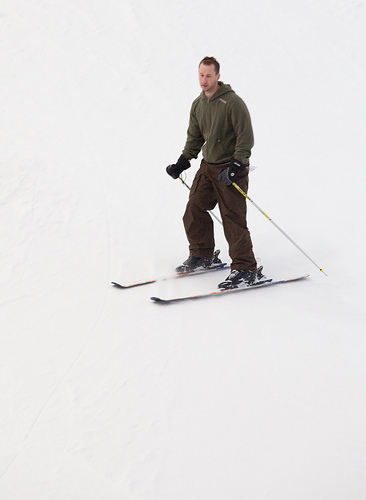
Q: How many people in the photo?
A: One.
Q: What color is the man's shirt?
A: Green.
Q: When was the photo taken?
A: Day time.